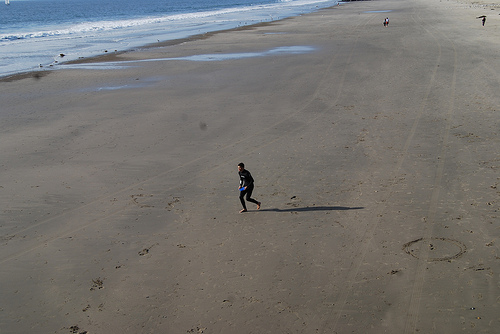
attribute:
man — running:
[238, 152, 253, 210]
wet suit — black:
[234, 174, 261, 209]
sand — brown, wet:
[182, 104, 196, 125]